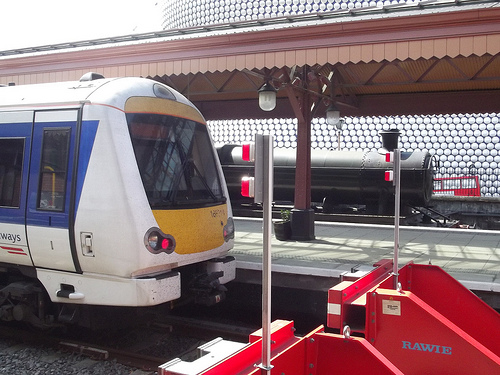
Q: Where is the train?
A: On the track.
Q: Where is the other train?
A: On the other track.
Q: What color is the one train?
A: White, yellow, and blue.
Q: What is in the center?
A: A cover for the passengers.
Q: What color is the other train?
A: Black.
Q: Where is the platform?
A: Between two trains.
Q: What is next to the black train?
A: A building.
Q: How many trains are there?
A: Two.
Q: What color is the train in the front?
A: Yellow.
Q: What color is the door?
A: Blue and white.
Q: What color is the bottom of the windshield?
A: Yellow.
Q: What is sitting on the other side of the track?
A: Black and grey train.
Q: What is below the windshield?
A: Headlights.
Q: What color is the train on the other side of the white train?
A: Black and gray.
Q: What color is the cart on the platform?
A: Red.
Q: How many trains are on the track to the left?
A: 1.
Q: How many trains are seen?
A: Two.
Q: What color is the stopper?
A: Red.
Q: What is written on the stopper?
A: Rawie.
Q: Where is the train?
A: On the track.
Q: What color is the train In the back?
A: Black.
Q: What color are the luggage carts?
A: Red.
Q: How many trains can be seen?
A: Two.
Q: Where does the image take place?
A: At a train station.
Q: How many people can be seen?
A: Zero.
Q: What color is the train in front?
A: White, yellow and blue.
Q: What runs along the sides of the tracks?
A: A sidewalk.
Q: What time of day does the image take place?
A: Daytime.